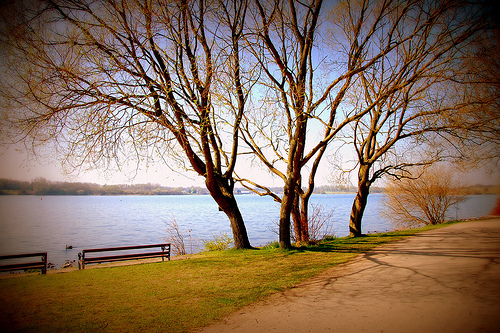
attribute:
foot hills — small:
[25, 176, 177, 196]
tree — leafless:
[0, 0, 264, 250]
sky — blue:
[2, 2, 498, 185]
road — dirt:
[288, 247, 442, 323]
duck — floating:
[54, 236, 78, 259]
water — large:
[93, 181, 237, 236]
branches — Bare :
[105, 40, 267, 181]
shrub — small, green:
[203, 235, 237, 255]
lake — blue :
[0, 190, 500, 270]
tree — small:
[334, 3, 499, 250]